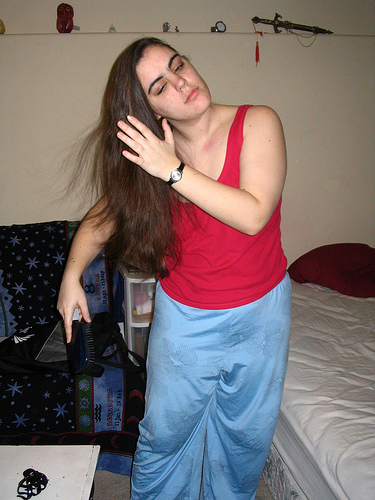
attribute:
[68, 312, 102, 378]
brush — blue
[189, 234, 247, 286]
shirt — red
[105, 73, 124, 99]
hair — brown, long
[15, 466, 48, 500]
tape — black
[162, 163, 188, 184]
wristwatch — black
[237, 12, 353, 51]
sword — small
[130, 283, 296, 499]
pants — blue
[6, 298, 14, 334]
towel — blue, black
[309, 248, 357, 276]
pillow — red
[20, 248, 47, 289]
stars — blue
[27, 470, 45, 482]
hair clip — black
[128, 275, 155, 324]
storage unit — plastic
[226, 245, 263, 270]
tank top — red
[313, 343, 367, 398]
sheet — white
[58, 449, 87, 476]
table top — white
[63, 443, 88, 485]
table — white